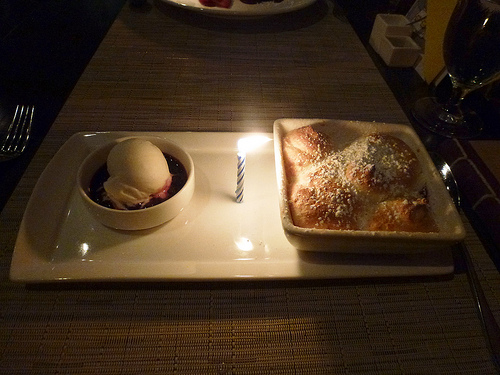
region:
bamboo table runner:
[26, 3, 476, 371]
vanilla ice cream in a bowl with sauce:
[68, 120, 200, 239]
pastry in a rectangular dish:
[271, 109, 468, 280]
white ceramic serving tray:
[8, 115, 460, 303]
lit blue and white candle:
[223, 125, 273, 207]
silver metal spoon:
[420, 145, 499, 337]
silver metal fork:
[3, 87, 38, 198]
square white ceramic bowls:
[363, 11, 428, 73]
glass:
[424, 9, 494, 151]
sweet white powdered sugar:
[343, 130, 386, 167]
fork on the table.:
[6, 94, 34, 148]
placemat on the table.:
[165, 318, 303, 358]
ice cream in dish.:
[122, 147, 157, 184]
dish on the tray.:
[70, 148, 202, 210]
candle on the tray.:
[229, 131, 256, 197]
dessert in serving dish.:
[325, 138, 384, 201]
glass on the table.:
[447, 17, 479, 119]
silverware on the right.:
[446, 160, 485, 300]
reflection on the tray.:
[214, 214, 260, 254]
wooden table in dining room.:
[53, 16, 94, 56]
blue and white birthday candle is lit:
[235, 132, 268, 202]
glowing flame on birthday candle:
[235, 132, 273, 154]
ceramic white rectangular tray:
[9, 126, 457, 278]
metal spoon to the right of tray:
[436, 157, 498, 346]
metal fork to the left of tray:
[0, 104, 32, 190]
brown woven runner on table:
[3, 1, 497, 373]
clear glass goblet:
[412, 0, 497, 139]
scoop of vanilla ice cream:
[103, 137, 174, 207]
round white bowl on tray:
[71, 136, 198, 233]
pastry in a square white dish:
[272, 115, 467, 264]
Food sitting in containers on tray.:
[14, 96, 469, 316]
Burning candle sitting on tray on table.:
[213, 121, 270, 214]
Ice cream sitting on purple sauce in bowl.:
[71, 126, 200, 233]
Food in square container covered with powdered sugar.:
[262, 107, 470, 248]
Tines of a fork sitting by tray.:
[3, 95, 37, 172]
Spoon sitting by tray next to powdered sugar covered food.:
[436, 146, 483, 356]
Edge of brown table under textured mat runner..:
[11, 20, 72, 93]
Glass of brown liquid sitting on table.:
[405, 0, 497, 150]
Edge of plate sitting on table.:
[141, 1, 311, 21]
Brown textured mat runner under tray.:
[32, 307, 448, 357]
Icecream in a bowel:
[71, 133, 210, 250]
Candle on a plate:
[214, 136, 279, 216]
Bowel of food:
[268, 101, 468, 249]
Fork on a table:
[7, 98, 39, 177]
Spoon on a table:
[408, 136, 498, 283]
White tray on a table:
[40, 103, 449, 310]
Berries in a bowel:
[83, 121, 246, 238]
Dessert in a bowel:
[283, 122, 423, 225]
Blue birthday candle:
[214, 126, 257, 218]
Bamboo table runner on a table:
[55, 296, 432, 373]